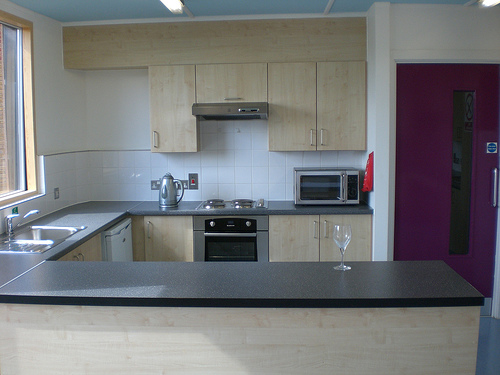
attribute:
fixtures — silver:
[2, 202, 84, 258]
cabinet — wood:
[317, 60, 367, 151]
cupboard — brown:
[267, 59, 391, 168]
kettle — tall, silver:
[157, 172, 184, 219]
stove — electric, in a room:
[192, 194, 270, 261]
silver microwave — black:
[292, 166, 359, 208]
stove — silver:
[202, 194, 267, 265]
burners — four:
[204, 197, 256, 216]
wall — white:
[58, 71, 148, 139]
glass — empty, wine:
[329, 219, 354, 273]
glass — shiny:
[326, 222, 363, 282]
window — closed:
[2, 24, 23, 195]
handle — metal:
[306, 216, 318, 249]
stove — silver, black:
[202, 191, 314, 263]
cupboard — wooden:
[268, 63, 368, 151]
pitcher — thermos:
[154, 168, 185, 218]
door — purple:
[395, 59, 500, 299]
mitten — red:
[360, 150, 375, 191]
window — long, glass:
[450, 88, 475, 259]